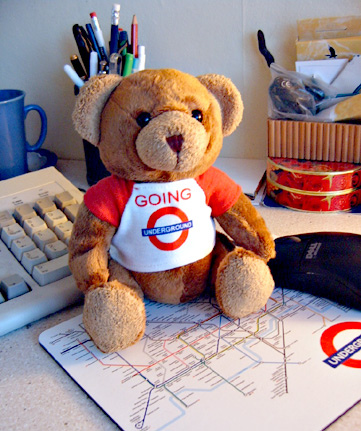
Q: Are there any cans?
A: Yes, there is a can.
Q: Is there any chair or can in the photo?
A: Yes, there is a can.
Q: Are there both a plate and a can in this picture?
A: Yes, there are both a can and a plate.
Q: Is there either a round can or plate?
A: Yes, there is a round can.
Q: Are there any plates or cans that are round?
A: Yes, the can is round.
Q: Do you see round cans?
A: Yes, there is a round can.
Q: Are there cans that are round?
A: Yes, there is a can that is round.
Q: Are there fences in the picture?
A: No, there are no fences.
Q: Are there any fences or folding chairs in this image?
A: No, there are no fences or folding chairs.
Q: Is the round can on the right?
A: Yes, the can is on the right of the image.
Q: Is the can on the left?
A: No, the can is on the right of the image.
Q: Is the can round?
A: Yes, the can is round.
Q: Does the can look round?
A: Yes, the can is round.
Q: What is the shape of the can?
A: The can is round.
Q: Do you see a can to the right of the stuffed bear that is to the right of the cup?
A: Yes, there is a can to the right of the stuffed bear.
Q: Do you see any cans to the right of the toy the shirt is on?
A: Yes, there is a can to the right of the stuffed bear.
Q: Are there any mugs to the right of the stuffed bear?
A: No, there is a can to the right of the stuffed bear.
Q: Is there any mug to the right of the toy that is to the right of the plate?
A: No, there is a can to the right of the stuffed bear.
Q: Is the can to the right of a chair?
A: No, the can is to the right of the stuffed bear.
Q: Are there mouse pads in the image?
A: Yes, there is a mouse pad.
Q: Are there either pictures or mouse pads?
A: Yes, there is a mouse pad.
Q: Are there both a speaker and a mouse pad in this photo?
A: No, there is a mouse pad but no speakers.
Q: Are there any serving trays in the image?
A: No, there are no serving trays.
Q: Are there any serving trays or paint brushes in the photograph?
A: No, there are no serving trays or paint brushes.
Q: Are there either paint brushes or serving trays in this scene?
A: No, there are no serving trays or paint brushes.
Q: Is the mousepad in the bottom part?
A: Yes, the mousepad is in the bottom of the image.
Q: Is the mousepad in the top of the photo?
A: No, the mousepad is in the bottom of the image.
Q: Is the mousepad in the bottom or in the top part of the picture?
A: The mousepad is in the bottom of the image.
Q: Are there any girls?
A: No, there are no girls.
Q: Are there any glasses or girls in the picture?
A: No, there are no girls or glasses.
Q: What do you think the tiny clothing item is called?
A: The clothing item is a shirt.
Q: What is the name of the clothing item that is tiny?
A: The clothing item is a shirt.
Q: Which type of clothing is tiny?
A: The clothing is a shirt.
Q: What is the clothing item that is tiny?
A: The clothing item is a shirt.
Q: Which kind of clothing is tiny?
A: The clothing is a shirt.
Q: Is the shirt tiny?
A: Yes, the shirt is tiny.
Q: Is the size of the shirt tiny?
A: Yes, the shirt is tiny.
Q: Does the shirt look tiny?
A: Yes, the shirt is tiny.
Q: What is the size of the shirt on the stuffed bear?
A: The shirt is tiny.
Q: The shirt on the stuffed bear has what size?
A: The shirt is tiny.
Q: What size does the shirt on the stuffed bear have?
A: The shirt has tiny size.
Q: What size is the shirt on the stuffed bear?
A: The shirt is tiny.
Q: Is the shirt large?
A: No, the shirt is tiny.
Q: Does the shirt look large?
A: No, the shirt is tiny.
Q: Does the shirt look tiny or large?
A: The shirt is tiny.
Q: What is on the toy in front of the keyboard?
A: The shirt is on the stuffed bear.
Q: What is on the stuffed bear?
A: The shirt is on the stuffed bear.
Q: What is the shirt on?
A: The shirt is on the stuffed bear.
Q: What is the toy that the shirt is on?
A: The toy is a stuffed bear.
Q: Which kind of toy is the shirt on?
A: The shirt is on the stuffed bear.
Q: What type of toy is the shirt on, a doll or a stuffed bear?
A: The shirt is on a stuffed bear.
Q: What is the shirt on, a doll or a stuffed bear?
A: The shirt is on a stuffed bear.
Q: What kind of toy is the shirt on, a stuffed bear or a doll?
A: The shirt is on a stuffed bear.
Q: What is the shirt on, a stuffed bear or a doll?
A: The shirt is on a stuffed bear.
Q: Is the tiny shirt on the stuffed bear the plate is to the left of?
A: Yes, the shirt is on the stuffed bear.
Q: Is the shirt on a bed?
A: No, the shirt is on the stuffed bear.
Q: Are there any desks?
A: Yes, there is a desk.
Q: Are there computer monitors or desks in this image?
A: Yes, there is a desk.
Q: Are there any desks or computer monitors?
A: Yes, there is a desk.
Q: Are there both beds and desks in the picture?
A: No, there is a desk but no beds.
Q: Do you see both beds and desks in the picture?
A: No, there is a desk but no beds.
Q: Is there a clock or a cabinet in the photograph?
A: No, there are no clocks or cabinets.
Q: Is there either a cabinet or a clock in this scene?
A: No, there are no clocks or cabinets.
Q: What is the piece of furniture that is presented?
A: The piece of furniture is a desk.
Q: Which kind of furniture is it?
A: The piece of furniture is a desk.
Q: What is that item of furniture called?
A: This is a desk.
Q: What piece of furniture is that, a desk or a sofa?
A: This is a desk.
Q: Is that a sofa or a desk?
A: That is a desk.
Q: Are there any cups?
A: Yes, there is a cup.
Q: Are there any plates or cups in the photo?
A: Yes, there is a cup.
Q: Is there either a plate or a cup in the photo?
A: Yes, there is a cup.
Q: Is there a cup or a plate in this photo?
A: Yes, there is a cup.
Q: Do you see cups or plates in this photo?
A: Yes, there is a cup.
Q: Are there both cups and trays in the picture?
A: No, there is a cup but no trays.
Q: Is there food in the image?
A: No, there is no food.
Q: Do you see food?
A: No, there is no food.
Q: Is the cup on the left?
A: Yes, the cup is on the left of the image.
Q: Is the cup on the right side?
A: No, the cup is on the left of the image.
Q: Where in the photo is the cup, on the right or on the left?
A: The cup is on the left of the image.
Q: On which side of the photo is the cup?
A: The cup is on the left of the image.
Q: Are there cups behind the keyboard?
A: Yes, there is a cup behind the keyboard.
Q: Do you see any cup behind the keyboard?
A: Yes, there is a cup behind the keyboard.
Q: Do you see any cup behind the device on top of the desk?
A: Yes, there is a cup behind the keyboard.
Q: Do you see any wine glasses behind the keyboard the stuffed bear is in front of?
A: No, there is a cup behind the keyboard.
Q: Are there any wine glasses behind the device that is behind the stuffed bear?
A: No, there is a cup behind the keyboard.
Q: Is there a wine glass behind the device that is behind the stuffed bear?
A: No, there is a cup behind the keyboard.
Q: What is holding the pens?
A: The cup is holding the pens.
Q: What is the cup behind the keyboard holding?
A: The cup is holding the pens.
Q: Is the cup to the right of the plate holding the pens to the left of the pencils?
A: Yes, the cup is holding the pens.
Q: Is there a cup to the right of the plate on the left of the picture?
A: Yes, there is a cup to the right of the plate.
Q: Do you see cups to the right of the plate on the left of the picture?
A: Yes, there is a cup to the right of the plate.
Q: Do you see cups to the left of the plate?
A: No, the cup is to the right of the plate.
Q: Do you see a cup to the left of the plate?
A: No, the cup is to the right of the plate.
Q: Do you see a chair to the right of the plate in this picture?
A: No, there is a cup to the right of the plate.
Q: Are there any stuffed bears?
A: Yes, there is a stuffed bear.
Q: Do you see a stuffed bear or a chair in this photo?
A: Yes, there is a stuffed bear.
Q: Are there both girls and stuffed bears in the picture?
A: No, there is a stuffed bear but no girls.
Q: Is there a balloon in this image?
A: No, there are no balloons.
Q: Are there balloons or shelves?
A: No, there are no balloons or shelves.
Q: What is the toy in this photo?
A: The toy is a stuffed bear.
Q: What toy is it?
A: The toy is a stuffed bear.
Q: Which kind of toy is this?
A: This is a stuffed bear.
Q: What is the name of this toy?
A: This is a stuffed bear.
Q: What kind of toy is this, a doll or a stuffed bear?
A: This is a stuffed bear.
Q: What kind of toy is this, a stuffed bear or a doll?
A: This is a stuffed bear.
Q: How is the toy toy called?
A: The toy is a stuffed bear.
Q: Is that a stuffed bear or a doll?
A: That is a stuffed bear.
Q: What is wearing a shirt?
A: The stuffed bear is wearing a shirt.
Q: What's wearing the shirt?
A: The stuffed bear is wearing a shirt.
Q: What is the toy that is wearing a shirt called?
A: The toy is a stuffed bear.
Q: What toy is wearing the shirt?
A: The toy is a stuffed bear.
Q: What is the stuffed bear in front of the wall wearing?
A: The stuffed bear is wearing a shirt.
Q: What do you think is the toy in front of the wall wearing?
A: The stuffed bear is wearing a shirt.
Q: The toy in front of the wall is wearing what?
A: The stuffed bear is wearing a shirt.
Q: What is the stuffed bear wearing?
A: The stuffed bear is wearing a shirt.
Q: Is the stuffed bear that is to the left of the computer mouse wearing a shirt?
A: Yes, the stuffed bear is wearing a shirt.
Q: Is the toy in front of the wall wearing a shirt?
A: Yes, the stuffed bear is wearing a shirt.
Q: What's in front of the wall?
A: The stuffed bear is in front of the wall.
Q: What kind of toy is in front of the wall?
A: The toy is a stuffed bear.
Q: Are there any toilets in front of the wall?
A: No, there is a stuffed bear in front of the wall.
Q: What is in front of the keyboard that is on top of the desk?
A: The stuffed bear is in front of the keyboard.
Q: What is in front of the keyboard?
A: The stuffed bear is in front of the keyboard.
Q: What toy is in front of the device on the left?
A: The toy is a stuffed bear.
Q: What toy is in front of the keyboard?
A: The toy is a stuffed bear.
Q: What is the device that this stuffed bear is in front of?
A: The device is a keyboard.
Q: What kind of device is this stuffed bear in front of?
A: The stuffed bear is in front of the keyboard.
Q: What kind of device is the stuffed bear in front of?
A: The stuffed bear is in front of the keyboard.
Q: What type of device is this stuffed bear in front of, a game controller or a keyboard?
A: The stuffed bear is in front of a keyboard.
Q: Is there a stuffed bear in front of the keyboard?
A: Yes, there is a stuffed bear in front of the keyboard.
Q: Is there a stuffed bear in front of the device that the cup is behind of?
A: Yes, there is a stuffed bear in front of the keyboard.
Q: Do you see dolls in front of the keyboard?
A: No, there is a stuffed bear in front of the keyboard.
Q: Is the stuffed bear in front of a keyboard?
A: Yes, the stuffed bear is in front of a keyboard.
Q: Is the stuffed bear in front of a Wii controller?
A: No, the stuffed bear is in front of a keyboard.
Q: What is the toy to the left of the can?
A: The toy is a stuffed bear.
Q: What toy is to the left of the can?
A: The toy is a stuffed bear.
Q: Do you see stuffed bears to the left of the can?
A: Yes, there is a stuffed bear to the left of the can.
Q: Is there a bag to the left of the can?
A: No, there is a stuffed bear to the left of the can.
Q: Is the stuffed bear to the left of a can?
A: Yes, the stuffed bear is to the left of a can.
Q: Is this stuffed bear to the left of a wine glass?
A: No, the stuffed bear is to the left of a can.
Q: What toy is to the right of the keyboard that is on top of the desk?
A: The toy is a stuffed bear.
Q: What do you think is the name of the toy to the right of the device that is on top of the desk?
A: The toy is a stuffed bear.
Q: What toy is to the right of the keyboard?
A: The toy is a stuffed bear.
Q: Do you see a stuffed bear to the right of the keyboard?
A: Yes, there is a stuffed bear to the right of the keyboard.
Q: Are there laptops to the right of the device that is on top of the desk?
A: No, there is a stuffed bear to the right of the keyboard.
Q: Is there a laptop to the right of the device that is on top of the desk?
A: No, there is a stuffed bear to the right of the keyboard.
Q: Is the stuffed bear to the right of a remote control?
A: No, the stuffed bear is to the right of the keyboard.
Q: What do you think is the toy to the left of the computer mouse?
A: The toy is a stuffed bear.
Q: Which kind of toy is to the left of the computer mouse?
A: The toy is a stuffed bear.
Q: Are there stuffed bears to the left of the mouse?
A: Yes, there is a stuffed bear to the left of the mouse.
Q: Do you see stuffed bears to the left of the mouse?
A: Yes, there is a stuffed bear to the left of the mouse.